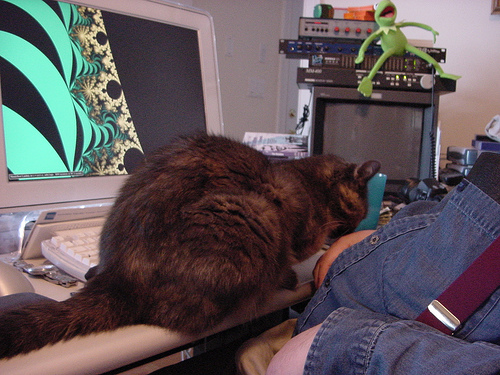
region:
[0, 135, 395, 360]
calico cat on computer keyboard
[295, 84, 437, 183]
small television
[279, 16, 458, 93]
cable and video components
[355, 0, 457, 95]
kermit the frog character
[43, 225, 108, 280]
white computer keyboard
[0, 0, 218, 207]
computer monitor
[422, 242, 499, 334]
maroon nylon strap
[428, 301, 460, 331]
silver metal buckle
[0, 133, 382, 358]
cat lying on desk and computer keyboard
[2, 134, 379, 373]
calico cat sleeping on counter ready to fall off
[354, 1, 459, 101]
Kermit the frog doll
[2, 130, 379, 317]
Dark colored cat on desk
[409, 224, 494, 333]
Purple suspender with metal clip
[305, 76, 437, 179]
Television on other side of person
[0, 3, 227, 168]
Computer monitor on desk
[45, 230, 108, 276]
Part of keyboard on desk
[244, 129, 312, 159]
Book lying near television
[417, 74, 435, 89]
Large silver knob on player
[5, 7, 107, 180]
Green and black fractal design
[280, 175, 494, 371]
Denim shirt on person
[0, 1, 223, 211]
computer moniter with white frame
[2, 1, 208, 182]
image on computer screen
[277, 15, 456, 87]
four electronics in a stack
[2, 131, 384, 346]
cat on edge of desk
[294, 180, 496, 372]
front of denim shirt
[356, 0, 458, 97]
frog toy on electronics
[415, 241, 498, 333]
suspender with silver buckle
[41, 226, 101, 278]
white buttons on keyboard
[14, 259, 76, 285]
silver watch on table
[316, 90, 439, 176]
blank screen on television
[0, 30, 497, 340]
The cat is in somebody's house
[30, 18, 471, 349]
The cat is wanting to be petted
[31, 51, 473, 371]
The cat is wanting to be fed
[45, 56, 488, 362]
The cat is close to its master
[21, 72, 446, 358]
The cat is sitting on a table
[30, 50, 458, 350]
The cat is out in the daytime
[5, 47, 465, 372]
The cat is in front of a keyboard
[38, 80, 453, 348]
The cat is having a great time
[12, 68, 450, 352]
The cat is enjoying the day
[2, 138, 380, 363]
a brown cat on a computer desk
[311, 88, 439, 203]
a gray TV on a desk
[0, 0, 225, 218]
a white computer monitor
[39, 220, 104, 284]
edge of a white keyboard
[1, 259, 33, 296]
a silver computer mouse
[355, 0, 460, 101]
a Kermit doll on top of a TV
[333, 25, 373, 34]
red knobs on a gray machine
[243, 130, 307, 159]
papers behind a TV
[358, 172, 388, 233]
a blue plastic glass on a desk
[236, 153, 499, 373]
a person sitting at a desk